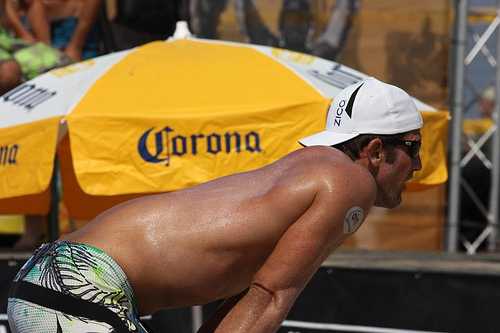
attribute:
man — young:
[73, 140, 408, 331]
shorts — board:
[3, 240, 136, 332]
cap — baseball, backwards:
[298, 76, 424, 146]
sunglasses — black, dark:
[385, 133, 425, 155]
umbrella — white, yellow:
[3, 13, 467, 195]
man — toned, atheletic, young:
[15, 86, 452, 323]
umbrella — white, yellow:
[9, 51, 461, 241]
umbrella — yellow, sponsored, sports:
[2, 15, 457, 225]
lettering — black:
[330, 94, 351, 126]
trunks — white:
[9, 235, 151, 332]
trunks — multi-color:
[28, 239, 160, 330]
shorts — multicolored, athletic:
[5, 237, 151, 331]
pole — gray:
[443, 0, 467, 255]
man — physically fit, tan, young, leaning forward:
[3, 75, 430, 331]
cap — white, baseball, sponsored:
[292, 77, 426, 150]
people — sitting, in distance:
[1, 2, 112, 75]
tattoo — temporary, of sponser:
[340, 202, 367, 235]